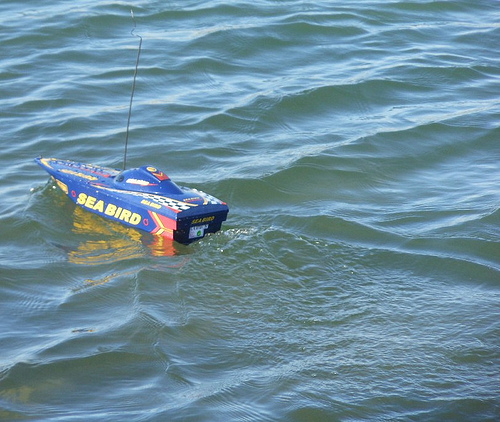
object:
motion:
[189, 227, 500, 421]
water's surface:
[0, 0, 499, 421]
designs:
[188, 225, 203, 239]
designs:
[58, 169, 98, 180]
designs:
[152, 171, 169, 180]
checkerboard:
[155, 185, 227, 213]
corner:
[146, 187, 228, 231]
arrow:
[152, 212, 165, 234]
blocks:
[148, 211, 177, 238]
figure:
[146, 167, 157, 172]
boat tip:
[35, 155, 73, 175]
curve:
[40, 158, 56, 169]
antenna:
[123, 7, 141, 165]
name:
[77, 192, 141, 224]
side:
[35, 160, 177, 238]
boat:
[36, 155, 228, 246]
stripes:
[148, 210, 161, 233]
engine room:
[114, 166, 183, 195]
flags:
[193, 189, 226, 205]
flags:
[94, 185, 196, 212]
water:
[0, 0, 499, 421]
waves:
[9, 311, 147, 371]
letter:
[129, 213, 141, 226]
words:
[77, 192, 104, 212]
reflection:
[70, 205, 173, 264]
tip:
[130, 9, 142, 39]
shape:
[34, 156, 229, 246]